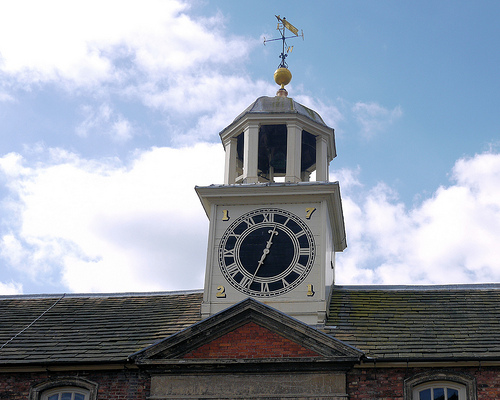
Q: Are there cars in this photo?
A: No, there are no cars.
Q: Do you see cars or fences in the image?
A: No, there are no cars or fences.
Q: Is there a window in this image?
A: Yes, there is a window.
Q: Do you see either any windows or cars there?
A: Yes, there is a window.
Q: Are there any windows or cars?
A: Yes, there is a window.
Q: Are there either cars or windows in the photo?
A: Yes, there is a window.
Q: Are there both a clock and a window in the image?
A: Yes, there are both a window and a clock.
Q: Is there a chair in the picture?
A: No, there are no chairs.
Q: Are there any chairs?
A: No, there are no chairs.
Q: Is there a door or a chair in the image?
A: No, there are no chairs or doors.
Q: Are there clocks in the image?
A: Yes, there is a clock.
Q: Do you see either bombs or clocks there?
A: Yes, there is a clock.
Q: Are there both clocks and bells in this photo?
A: No, there is a clock but no bells.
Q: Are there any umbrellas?
A: No, there are no umbrellas.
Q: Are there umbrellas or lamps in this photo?
A: No, there are no umbrellas or lamps.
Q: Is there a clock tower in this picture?
A: Yes, there is a clock tower.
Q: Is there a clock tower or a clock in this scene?
A: Yes, there is a clock tower.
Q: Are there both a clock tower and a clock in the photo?
A: Yes, there are both a clock tower and a clock.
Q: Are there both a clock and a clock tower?
A: Yes, there are both a clock tower and a clock.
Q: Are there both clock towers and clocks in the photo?
A: Yes, there are both a clock tower and a clock.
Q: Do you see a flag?
A: No, there are no flags.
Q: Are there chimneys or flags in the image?
A: No, there are no flags or chimneys.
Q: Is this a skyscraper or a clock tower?
A: This is a clock tower.